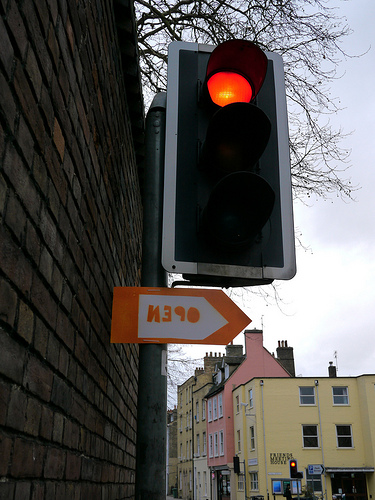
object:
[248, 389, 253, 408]
window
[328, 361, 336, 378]
building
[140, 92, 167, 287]
pole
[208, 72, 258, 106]
red light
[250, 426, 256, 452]
window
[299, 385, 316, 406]
small window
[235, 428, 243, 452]
window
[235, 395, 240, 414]
window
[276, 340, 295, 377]
building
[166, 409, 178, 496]
building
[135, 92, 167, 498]
pole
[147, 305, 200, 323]
writing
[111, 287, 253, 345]
arrow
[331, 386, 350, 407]
window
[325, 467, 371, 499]
doors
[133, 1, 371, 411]
tree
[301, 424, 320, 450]
small window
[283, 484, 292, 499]
person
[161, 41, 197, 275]
border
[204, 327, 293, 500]
building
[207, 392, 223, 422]
window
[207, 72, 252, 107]
light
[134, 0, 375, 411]
sky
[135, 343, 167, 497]
pole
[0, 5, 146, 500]
wall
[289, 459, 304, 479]
traffic light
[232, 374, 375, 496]
building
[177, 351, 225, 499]
building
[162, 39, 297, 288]
sign